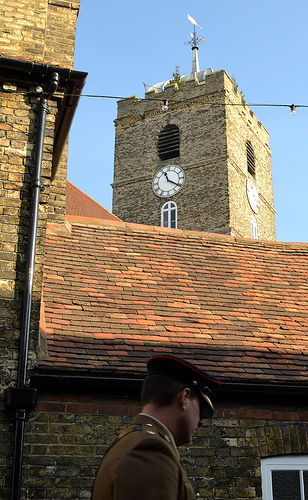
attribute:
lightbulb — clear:
[290, 110, 295, 115]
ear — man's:
[178, 384, 191, 409]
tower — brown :
[82, 31, 307, 264]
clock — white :
[155, 161, 183, 197]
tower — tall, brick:
[102, 11, 277, 237]